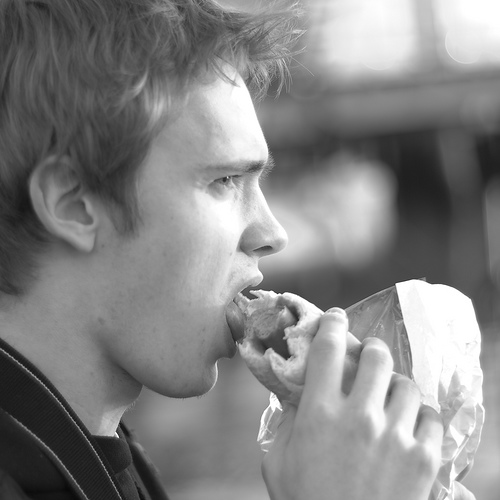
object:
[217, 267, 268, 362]
mouth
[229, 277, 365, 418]
food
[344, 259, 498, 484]
wrapper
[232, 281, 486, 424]
sandwich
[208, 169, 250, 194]
eye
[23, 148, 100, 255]
ear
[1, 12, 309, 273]
hair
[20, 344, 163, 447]
neck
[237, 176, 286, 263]
nose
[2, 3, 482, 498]
man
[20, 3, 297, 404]
face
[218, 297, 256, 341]
tongue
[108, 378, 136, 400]
fuzz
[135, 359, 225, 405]
chin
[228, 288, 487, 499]
bun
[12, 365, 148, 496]
strap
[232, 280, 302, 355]
sausage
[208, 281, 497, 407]
tongue food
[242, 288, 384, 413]
hot dog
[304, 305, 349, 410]
finger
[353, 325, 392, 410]
finger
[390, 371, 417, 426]
finger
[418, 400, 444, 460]
finger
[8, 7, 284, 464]
man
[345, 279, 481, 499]
package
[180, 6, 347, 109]
bangs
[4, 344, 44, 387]
trim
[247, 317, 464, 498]
hand